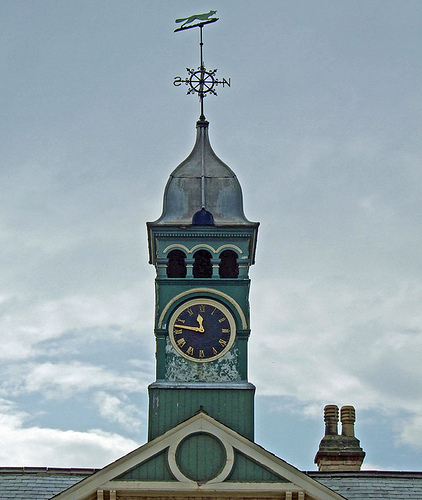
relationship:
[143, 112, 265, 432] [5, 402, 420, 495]
clock tower on building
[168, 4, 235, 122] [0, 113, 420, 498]
wind vane on building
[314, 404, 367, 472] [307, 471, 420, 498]
chimney on roof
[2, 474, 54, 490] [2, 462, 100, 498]
shingles on roof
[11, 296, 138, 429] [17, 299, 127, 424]
clouds in sky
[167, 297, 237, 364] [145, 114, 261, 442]
clock on clock tower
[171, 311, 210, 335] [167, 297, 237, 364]
hands on clock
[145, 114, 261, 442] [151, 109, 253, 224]
clock tower has doom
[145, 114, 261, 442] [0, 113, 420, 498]
clock tower on building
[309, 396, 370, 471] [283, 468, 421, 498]
chimney on roof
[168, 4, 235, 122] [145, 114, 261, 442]
wind vane on clock tower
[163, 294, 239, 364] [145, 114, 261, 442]
clock on clock tower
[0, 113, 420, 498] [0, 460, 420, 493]
building has roof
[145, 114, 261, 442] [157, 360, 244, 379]
clock tower has paint